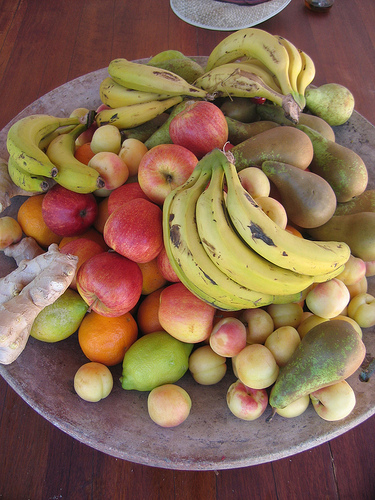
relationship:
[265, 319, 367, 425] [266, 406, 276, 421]
pear has stem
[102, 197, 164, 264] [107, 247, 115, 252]
apple has stem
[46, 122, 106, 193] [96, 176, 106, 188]
banana has end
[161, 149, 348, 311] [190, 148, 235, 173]
bananas have handle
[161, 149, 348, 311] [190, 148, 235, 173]
bananas in handle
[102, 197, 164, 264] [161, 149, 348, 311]
apple next to bananas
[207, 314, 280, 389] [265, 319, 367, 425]
peaches next to pear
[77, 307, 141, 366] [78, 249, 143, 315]
orange below apple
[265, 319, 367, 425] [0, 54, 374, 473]
pear on plate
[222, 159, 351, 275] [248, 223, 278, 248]
banana has bruise